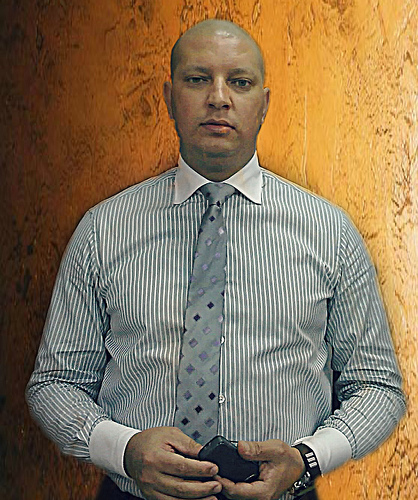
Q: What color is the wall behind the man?
A: Brown.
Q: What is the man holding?
A: A cell phone.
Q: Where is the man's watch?
A: His wrist.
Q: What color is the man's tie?
A: Gray.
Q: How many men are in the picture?
A: One.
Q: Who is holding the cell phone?
A: The man.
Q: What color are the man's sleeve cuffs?
A: White.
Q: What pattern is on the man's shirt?
A: Stripes.